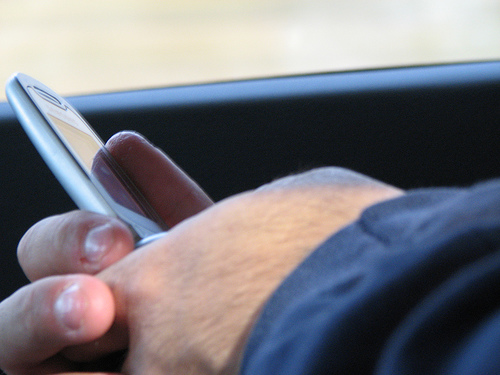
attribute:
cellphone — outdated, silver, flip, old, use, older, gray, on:
[6, 75, 166, 249]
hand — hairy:
[62, 164, 403, 372]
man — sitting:
[0, 118, 498, 369]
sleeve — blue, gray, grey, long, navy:
[235, 174, 499, 375]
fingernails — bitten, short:
[82, 220, 116, 260]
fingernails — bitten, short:
[54, 284, 83, 332]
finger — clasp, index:
[14, 213, 142, 283]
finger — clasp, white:
[105, 131, 214, 224]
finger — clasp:
[0, 268, 111, 373]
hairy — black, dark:
[144, 179, 365, 371]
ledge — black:
[6, 58, 494, 283]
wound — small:
[76, 253, 93, 265]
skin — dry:
[108, 136, 139, 162]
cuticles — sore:
[79, 219, 114, 264]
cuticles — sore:
[49, 278, 90, 338]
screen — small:
[46, 114, 154, 225]